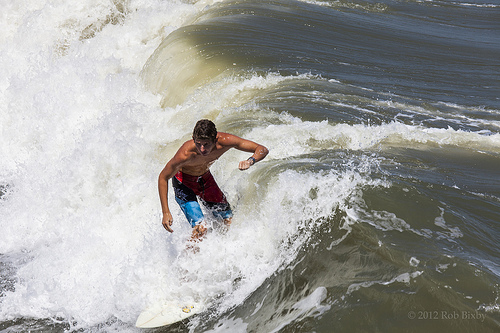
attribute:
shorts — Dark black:
[159, 171, 247, 241]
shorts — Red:
[167, 169, 239, 230]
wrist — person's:
[246, 153, 260, 165]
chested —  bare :
[178, 149, 218, 179]